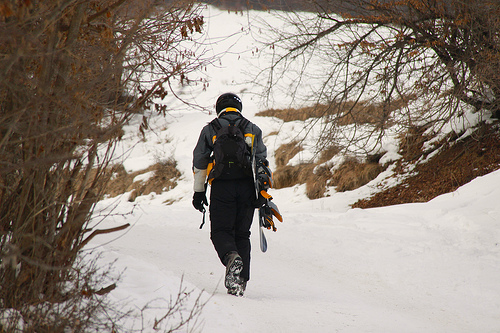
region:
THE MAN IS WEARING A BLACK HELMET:
[205, 87, 250, 112]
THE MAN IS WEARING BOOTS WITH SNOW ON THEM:
[216, 245, 247, 296]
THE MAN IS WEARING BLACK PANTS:
[200, 171, 258, 291]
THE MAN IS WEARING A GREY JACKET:
[188, 110, 269, 206]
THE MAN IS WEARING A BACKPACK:
[212, 120, 250, 192]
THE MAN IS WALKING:
[190, 81, 286, 304]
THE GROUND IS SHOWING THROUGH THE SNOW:
[342, 120, 497, 220]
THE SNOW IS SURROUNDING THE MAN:
[50, 23, 495, 328]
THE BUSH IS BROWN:
[0, 0, 235, 330]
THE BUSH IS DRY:
[246, 4, 498, 181]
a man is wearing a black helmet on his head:
[217, 90, 242, 114]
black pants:
[216, 183, 251, 259]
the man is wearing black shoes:
[221, 250, 256, 292]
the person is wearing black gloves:
[191, 190, 210, 208]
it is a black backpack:
[209, 128, 255, 189]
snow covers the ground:
[326, 232, 457, 326]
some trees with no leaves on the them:
[8, 30, 126, 295]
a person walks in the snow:
[173, 78, 308, 313]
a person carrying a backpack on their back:
[207, 125, 259, 187]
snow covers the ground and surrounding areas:
[156, 213, 338, 320]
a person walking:
[185, 93, 280, 303]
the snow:
[320, 222, 446, 307]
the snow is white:
[317, 223, 456, 323]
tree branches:
[319, 69, 409, 117]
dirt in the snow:
[119, 162, 176, 197]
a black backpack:
[210, 131, 250, 186]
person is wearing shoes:
[223, 258, 243, 294]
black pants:
[211, 196, 246, 248]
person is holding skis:
[245, 148, 265, 188]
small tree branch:
[163, 281, 220, 320]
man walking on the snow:
[162, 65, 319, 331]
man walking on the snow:
[196, 74, 268, 308]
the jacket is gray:
[181, 108, 285, 212]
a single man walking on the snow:
[186, 93, 276, 298]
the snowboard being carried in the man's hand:
[247, 143, 279, 254]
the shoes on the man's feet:
[218, 247, 248, 298]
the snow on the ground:
[108, 183, 485, 332]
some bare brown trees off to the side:
[4, 3, 141, 330]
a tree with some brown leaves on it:
[283, 12, 497, 117]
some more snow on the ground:
[161, 5, 380, 107]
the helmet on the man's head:
[210, 86, 242, 109]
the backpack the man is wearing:
[202, 120, 254, 181]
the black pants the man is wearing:
[207, 181, 257, 275]